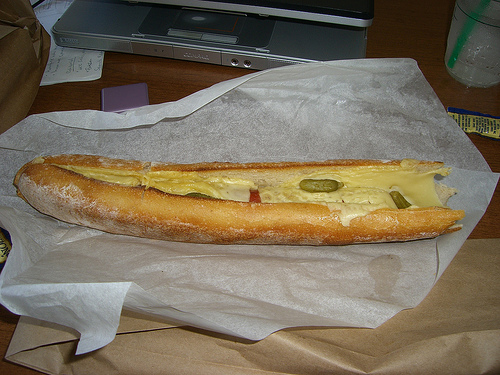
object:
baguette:
[12, 154, 466, 249]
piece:
[93, 81, 153, 116]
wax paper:
[0, 57, 499, 359]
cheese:
[161, 175, 197, 190]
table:
[20, 1, 500, 241]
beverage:
[440, 1, 499, 89]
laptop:
[50, 3, 376, 75]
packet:
[441, 104, 499, 142]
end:
[9, 153, 89, 228]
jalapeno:
[293, 175, 347, 195]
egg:
[323, 190, 391, 223]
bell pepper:
[243, 187, 262, 204]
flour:
[30, 189, 39, 199]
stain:
[366, 251, 406, 312]